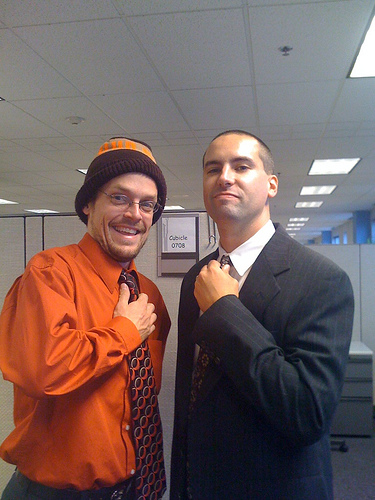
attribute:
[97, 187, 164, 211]
frame — metal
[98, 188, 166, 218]
glasses — small, circular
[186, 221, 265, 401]
shirt — clean, ironed, white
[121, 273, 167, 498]
circles — orange , white 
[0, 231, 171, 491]
shirt — bright, orange, long sleeve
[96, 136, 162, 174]
knit hat — Orange, brown, grey , knit 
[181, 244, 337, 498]
jacket — pinstriped, blue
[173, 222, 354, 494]
suit — grey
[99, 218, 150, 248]
smile — Big huge 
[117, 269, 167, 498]
tie — colorful